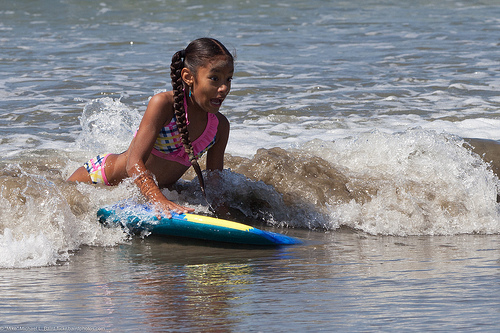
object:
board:
[97, 203, 306, 249]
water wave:
[1, 268, 498, 331]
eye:
[209, 76, 218, 82]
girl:
[63, 37, 233, 219]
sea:
[1, 1, 498, 331]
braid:
[170, 50, 206, 198]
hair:
[170, 37, 236, 198]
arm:
[131, 92, 173, 201]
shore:
[0, 241, 500, 331]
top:
[138, 89, 222, 168]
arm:
[205, 112, 230, 170]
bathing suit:
[80, 151, 110, 186]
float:
[97, 197, 310, 252]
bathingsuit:
[152, 109, 216, 167]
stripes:
[163, 120, 180, 154]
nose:
[218, 82, 227, 92]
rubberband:
[187, 156, 197, 161]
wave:
[0, 96, 497, 267]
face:
[193, 53, 234, 113]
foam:
[305, 83, 361, 113]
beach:
[0, 0, 499, 325]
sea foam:
[424, 114, 499, 147]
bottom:
[81, 151, 115, 184]